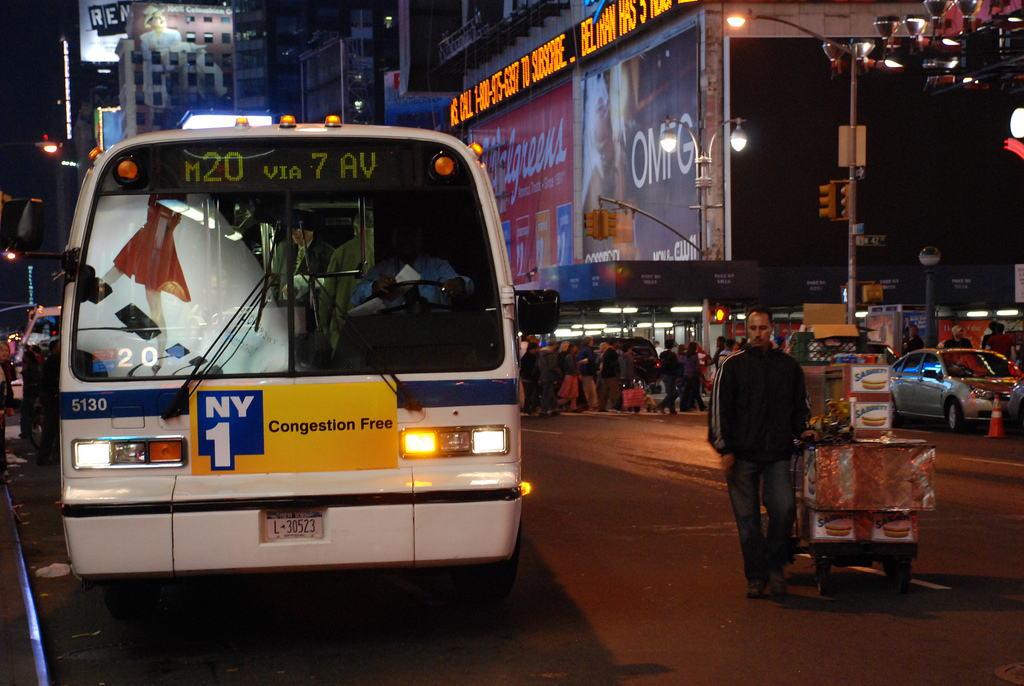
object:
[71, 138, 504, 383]
glass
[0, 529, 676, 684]
shadow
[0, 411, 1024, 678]
road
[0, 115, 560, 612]
bus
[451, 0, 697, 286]
billboard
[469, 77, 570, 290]
lettering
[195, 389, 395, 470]
lettering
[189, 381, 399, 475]
sign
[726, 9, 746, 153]
light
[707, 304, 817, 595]
man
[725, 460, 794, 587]
jeans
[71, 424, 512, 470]
headlights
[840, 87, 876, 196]
window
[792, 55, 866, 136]
window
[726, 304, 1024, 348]
window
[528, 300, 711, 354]
window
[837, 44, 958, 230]
window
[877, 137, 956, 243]
window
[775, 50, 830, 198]
window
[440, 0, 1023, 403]
building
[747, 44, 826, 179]
window